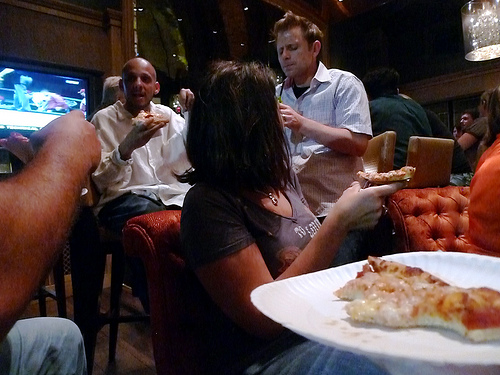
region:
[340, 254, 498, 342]
slices of pizza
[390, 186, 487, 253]
orange chair back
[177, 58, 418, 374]
woman eating slice of pizza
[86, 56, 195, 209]
man in white shirt eating pizza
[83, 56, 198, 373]
man sitting on stool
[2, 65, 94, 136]
boxing match on television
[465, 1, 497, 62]
interior light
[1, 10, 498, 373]
men and women in bar eating pizza and watching boxing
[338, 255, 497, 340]
cheese pizza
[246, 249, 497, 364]
white serving platter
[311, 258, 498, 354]
Pizza on a plate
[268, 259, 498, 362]
White plate with pizza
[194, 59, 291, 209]
Brown hair on a woman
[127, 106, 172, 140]
Pizza in a hand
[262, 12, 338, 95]
Brown hair on a man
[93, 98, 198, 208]
White shirt on a man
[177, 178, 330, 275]
Gray shirt on a woman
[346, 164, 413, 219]
Pizza in a woman's hand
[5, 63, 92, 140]
TV behind people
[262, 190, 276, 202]
Necklace on a woman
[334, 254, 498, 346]
"Half eaten piece of pizza"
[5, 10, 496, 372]
"People eating and drinking"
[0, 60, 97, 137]
"TV on the wall"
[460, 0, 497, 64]
"Silver light over a table"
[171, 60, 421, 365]
"Woman having fun and eating"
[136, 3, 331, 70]
"Track lighting on the ceiling"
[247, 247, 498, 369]
"White paper plate holding pizza"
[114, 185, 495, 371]
"Orange chairs people are lounging in"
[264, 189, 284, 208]
"Pendant around a woman's neck"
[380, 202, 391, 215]
"Ring on a woman's finger"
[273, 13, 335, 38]
Man has brown hair.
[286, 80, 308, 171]
Man wearing button down shirt.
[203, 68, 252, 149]
Person has dark hair.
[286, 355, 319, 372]
Person wearing blue jeans.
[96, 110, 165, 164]
Person wearing white shirt.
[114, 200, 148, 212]
Person wearing blue jeans.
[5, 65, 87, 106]
Large television behind people.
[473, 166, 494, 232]
Person wearing orange shirt.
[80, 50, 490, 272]
People in the restaurant.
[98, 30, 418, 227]
People eating pizza and talking.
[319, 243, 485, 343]
A piece of bitten into pizza on the plate.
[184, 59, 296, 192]
The lady have her head turned.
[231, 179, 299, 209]
The lady is wearing a necklace.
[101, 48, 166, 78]
The man has a bald head.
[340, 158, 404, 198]
The lady is holding a slice of pizza.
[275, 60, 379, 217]
white shirt is worn by human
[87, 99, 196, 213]
white shirt is worn by human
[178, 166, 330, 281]
shirt is worn by woman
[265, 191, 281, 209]
necklace is worn by human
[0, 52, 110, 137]
television is displaying sports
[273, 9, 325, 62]
hair is cut short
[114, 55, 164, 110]
head is bald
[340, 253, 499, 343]
pizza sits on round plate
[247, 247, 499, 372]
white plate supports pizza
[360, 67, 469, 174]
human sits on chair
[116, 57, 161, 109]
Head of a man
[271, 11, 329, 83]
Head of a man